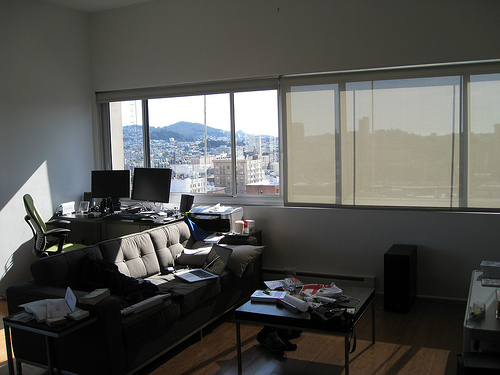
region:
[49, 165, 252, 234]
a messy desk by the window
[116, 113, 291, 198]
a good view of the city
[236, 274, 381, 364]
a dirty coffee table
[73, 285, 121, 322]
a book sitting on the arm of the couch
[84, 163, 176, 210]
two computer monitor's that are not turned on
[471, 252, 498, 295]
Wii games for the Wii game system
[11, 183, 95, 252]
lime green and black office chair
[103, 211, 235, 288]
sun shining on the couch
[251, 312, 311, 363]
pair of tennis shoes under the coffee table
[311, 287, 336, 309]
a white Wii controler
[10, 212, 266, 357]
Black laptop on a couch.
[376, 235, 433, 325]
Black speaker on the floor.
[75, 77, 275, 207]
Open window with a view.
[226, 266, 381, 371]
Table with a book on it.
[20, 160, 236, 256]
Desk with more than on computer.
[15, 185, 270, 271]
Chair in front of a desk.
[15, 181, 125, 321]
Green chair with armrests.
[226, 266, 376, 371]
Shoes under a table.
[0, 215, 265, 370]
Brown couch with a pillow.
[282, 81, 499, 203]
Curtains in front of a window.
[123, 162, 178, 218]
a computer monitor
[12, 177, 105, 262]
a green chair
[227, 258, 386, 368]
a coffee table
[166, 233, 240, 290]
a laptop computer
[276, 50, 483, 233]
a window with the blinds closed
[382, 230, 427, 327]
a speaker for the stereo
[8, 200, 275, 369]
a brown sofa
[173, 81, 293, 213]
a building in the background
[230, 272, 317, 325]
a book on the coffee table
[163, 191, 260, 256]
a printer for the computer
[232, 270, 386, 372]
A black coffee table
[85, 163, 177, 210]
Two black computer screens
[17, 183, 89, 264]
A green office chair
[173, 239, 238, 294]
One laptop on a couch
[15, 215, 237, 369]
A grey couch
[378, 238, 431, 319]
A black speaker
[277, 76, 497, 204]
White window shades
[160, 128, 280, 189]
A city view during the day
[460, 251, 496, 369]
A white television stand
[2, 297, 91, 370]
Living room end table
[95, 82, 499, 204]
Windows along a living room wall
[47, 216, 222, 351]
A grey couch in the living room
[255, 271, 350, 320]
Trash on the coffee table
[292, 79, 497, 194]
Cream window shades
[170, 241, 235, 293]
A laptop on the couch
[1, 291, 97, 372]
A black side table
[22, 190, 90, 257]
An office chair at a desk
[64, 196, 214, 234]
An office desk